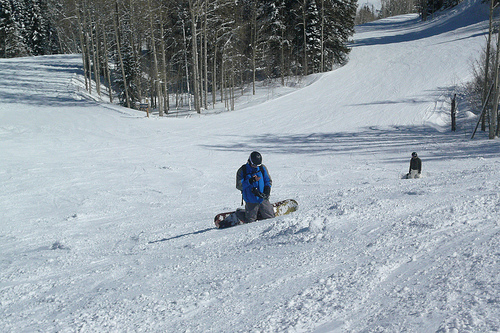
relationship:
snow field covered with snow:
[1, 50, 498, 329] [343, 253, 406, 308]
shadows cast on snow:
[3, 54, 86, 100] [25, 113, 104, 198]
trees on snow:
[60, 0, 364, 116] [3, 6, 494, 328]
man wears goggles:
[234, 150, 276, 223] [236, 160, 278, 178]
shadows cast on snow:
[317, 116, 439, 169] [386, 197, 433, 264]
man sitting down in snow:
[234, 150, 276, 223] [3, 6, 494, 328]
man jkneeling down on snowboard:
[234, 150, 276, 223] [199, 191, 354, 235]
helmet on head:
[247, 151, 262, 167] [247, 150, 264, 168]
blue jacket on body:
[235, 161, 273, 205] [204, 136, 309, 238]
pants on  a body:
[244, 199, 275, 222] [234, 151, 274, 223]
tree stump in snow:
[448, 93, 462, 133] [343, 225, 449, 290]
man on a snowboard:
[234, 150, 276, 223] [211, 193, 297, 230]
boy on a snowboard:
[406, 152, 422, 179] [400, 171, 414, 182]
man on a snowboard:
[234, 150, 276, 223] [214, 198, 298, 225]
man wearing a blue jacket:
[234, 150, 276, 223] [232, 163, 274, 198]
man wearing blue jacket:
[234, 150, 276, 223] [236, 157, 273, 204]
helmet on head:
[250, 153, 260, 164] [245, 152, 265, 166]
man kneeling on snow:
[234, 150, 276, 223] [92, 231, 470, 302]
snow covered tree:
[256, 35, 270, 70] [237, 2, 277, 94]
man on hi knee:
[234, 150, 276, 223] [238, 208, 261, 226]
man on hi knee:
[234, 150, 276, 223] [261, 202, 279, 218]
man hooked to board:
[234, 150, 276, 223] [212, 199, 302, 231]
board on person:
[214, 198, 300, 228] [201, 117, 282, 229]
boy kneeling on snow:
[406, 152, 422, 179] [3, 6, 494, 328]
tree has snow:
[3, 9, 33, 54] [2, 3, 11, 13]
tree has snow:
[3, 9, 33, 54] [15, 30, 27, 42]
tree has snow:
[3, 9, 33, 54] [4, 44, 14, 50]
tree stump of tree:
[449, 93, 460, 133] [149, 127, 195, 154]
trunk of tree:
[84, 30, 106, 96] [145, 77, 184, 116]